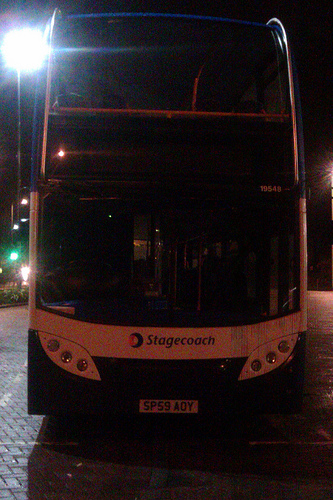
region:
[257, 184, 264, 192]
The number 1 on the front of the bus.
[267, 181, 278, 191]
The number 4 on the front of the bus.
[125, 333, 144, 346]
The design on the front of the bus above the license plate.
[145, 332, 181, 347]
The word Stage on the front of the bus.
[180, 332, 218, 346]
The word coach on the front of the bus.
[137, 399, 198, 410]
The license plate on the front of the bus.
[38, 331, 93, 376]
The three lights on the left side.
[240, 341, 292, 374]
The three lights on the right side.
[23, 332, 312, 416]
The black paint on the lower part of the front of the bus.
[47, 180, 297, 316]
The main front window on the front of the bus.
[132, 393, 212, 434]
White plate on front of bus.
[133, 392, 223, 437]
Black lettering in white plate.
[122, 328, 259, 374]
Stagecoach written on front of bus.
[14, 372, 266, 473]
Bus parked on brick ground.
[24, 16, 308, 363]
front of double decker bus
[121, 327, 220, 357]
logo of bus company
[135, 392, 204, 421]
license plate on bus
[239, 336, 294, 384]
three lights on bus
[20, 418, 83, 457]
shadow of bus on bricks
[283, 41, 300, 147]
metal pole on bus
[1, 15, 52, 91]
glowing light on pole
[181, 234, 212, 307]
pole inside of bus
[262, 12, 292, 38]
curved pole on bus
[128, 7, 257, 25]
blue roof on bus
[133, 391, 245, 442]
white plate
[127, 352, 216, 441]
white plate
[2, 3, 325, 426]
this is a big bus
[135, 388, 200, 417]
the number plate of the bus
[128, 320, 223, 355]
the name of the bus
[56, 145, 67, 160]
a small bright light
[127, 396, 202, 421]
writings on the bus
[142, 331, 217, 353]
writings on the bus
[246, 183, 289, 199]
writings on the bus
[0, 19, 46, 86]
the light is shining bright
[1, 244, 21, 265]
the light is green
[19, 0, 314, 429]
this a stagecoach bus